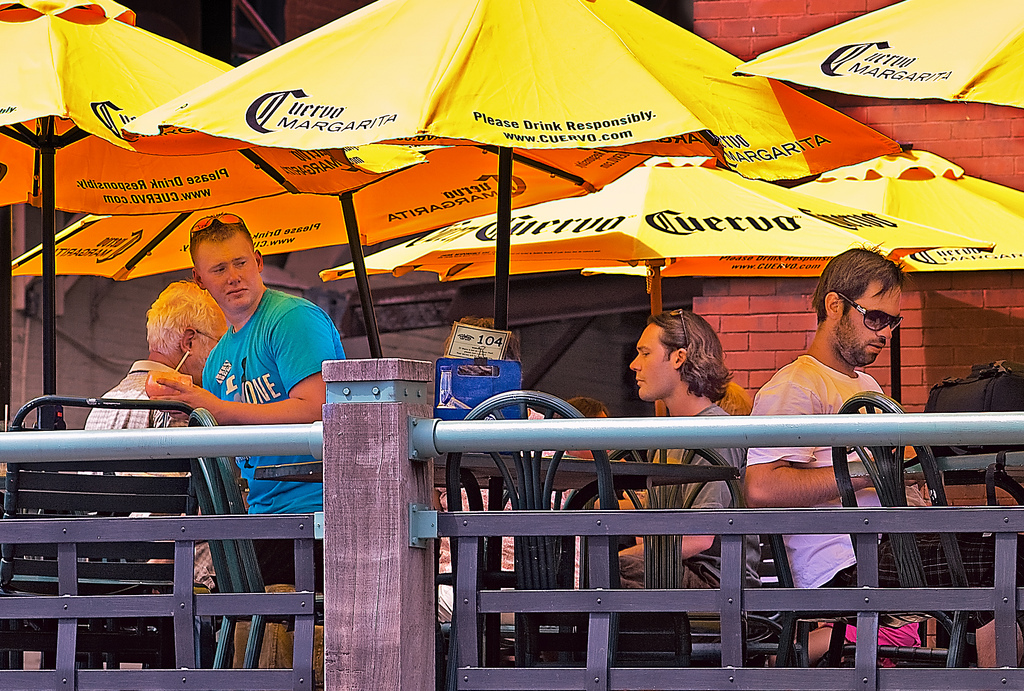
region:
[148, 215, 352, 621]
Sunglasses on man's head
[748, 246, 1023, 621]
Man wearing black sunglasses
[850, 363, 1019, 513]
Black bag on top of table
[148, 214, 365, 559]
Man holding a drink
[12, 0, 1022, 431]
All umbrellas are opened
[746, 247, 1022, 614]
Man wearing a white shirt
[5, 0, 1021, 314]
Umbrellas are orange and yellow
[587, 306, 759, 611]
Man with glasses on top of head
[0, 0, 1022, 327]
Writing on the umbrellas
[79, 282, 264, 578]
Man with grey hair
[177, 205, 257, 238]
Sunglasses on top of man's head.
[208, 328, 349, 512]
Man wearing bright blue shirt.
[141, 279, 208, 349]
Person has white hair.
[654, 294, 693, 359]
Sunglasses on person's head.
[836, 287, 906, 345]
Sunglasses on man's face.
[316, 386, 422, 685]
Wood post connected to metal pieces.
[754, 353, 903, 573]
Man wearing white shirt.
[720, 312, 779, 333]
A red brick on a building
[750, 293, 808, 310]
A red brick on a building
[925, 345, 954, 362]
A red brick on a building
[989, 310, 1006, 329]
A red brick on a building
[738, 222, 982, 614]
A person is sitting down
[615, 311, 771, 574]
A person is sitting down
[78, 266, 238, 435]
A person is sitting down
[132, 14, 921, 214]
A large open umbrella.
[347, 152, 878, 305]
A large open umbrella.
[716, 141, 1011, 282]
A large open umbrella.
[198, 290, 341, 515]
the shirt is blue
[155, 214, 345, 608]
the sunglasses on the man's head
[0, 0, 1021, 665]
the people under the umbrellas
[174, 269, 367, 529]
A blue short sleeved shirt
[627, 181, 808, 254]
"Cuervo" written in black letters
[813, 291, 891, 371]
Facial hair on the guy's face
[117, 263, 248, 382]
A man has white hair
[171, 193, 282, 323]
Sunglasses on a man's head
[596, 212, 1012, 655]
Two men sitting at tables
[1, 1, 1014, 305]
A bunch of open yellow umbrellas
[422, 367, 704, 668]
A black wooden chair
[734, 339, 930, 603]
A white short sleeved shirt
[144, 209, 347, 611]
the man wearing a blue shirt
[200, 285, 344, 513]
the shirt is blue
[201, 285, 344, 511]
the shirt is short sleeved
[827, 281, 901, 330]
the sunglasses are black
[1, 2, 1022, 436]
the opened umbrellas are yellow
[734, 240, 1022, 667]
the man is sitting down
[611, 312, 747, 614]
the man is sitting down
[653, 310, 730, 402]
the man has brown hair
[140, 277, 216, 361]
the hair is white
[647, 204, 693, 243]
A letter on an umbrella.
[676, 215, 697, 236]
A letter on an umbrella.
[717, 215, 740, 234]
A letter on an umbrella.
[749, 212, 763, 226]
A letter on an umbrella.